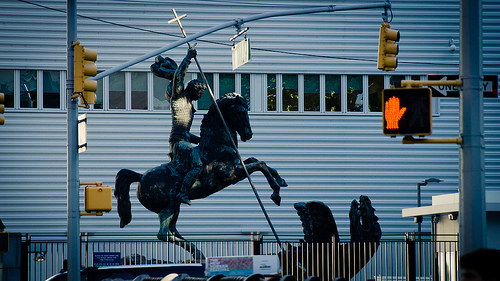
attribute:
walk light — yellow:
[369, 84, 477, 143]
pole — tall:
[53, 101, 94, 254]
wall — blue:
[294, 155, 394, 196]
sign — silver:
[178, 39, 276, 84]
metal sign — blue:
[88, 247, 134, 276]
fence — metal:
[78, 199, 454, 279]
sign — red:
[375, 87, 433, 137]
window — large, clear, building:
[283, 74, 298, 110]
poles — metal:
[20, 231, 478, 279]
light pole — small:
[411, 176, 445, 277]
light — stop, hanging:
[366, 21, 431, 90]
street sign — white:
[427, 73, 499, 95]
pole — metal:
[459, 0, 484, 280]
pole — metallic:
[456, 2, 489, 267]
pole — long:
[161, 4, 304, 254]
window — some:
[278, 73, 300, 113]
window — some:
[301, 73, 321, 114]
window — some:
[325, 72, 343, 114]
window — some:
[345, 72, 365, 112]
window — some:
[366, 72, 383, 112]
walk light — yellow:
[84, 180, 124, 209]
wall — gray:
[1, 1, 498, 241]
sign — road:
[230, 29, 250, 68]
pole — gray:
[83, 0, 399, 80]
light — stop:
[354, 3, 399, 83]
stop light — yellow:
[69, 40, 100, 108]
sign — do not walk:
[378, 78, 436, 139]